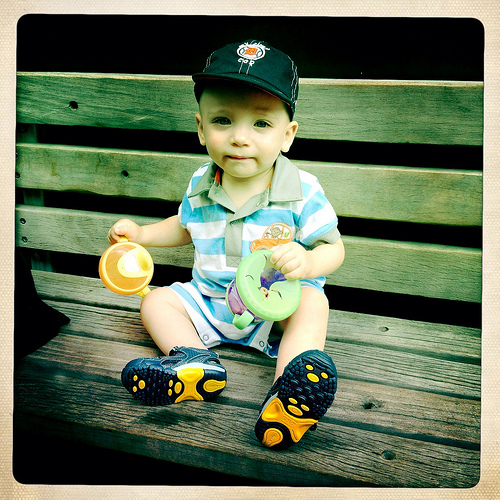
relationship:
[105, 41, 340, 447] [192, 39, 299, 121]
boy wearing baseball cap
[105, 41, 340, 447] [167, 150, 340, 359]
boy wearing onesie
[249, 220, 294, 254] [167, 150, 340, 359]
design sewed onto onesie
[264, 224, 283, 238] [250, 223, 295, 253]
monkey driving design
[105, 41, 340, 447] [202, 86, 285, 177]
boy has face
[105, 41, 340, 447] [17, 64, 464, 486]
boy sitting on bench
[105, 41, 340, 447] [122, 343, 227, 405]
boy has shoe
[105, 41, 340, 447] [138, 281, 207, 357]
boy has leg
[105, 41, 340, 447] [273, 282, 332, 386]
boy has leg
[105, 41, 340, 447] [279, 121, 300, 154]
boy has ear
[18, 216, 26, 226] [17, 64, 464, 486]
screws screwed in bench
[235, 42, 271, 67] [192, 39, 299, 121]
logo on front of baseball cap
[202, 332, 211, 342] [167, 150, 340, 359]
snap on front of onesie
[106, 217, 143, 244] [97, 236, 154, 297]
hand holding sippy cup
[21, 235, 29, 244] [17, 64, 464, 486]
screws screwed in bench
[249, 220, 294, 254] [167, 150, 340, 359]
design on front of onesie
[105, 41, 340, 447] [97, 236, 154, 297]
boy holding sippy cup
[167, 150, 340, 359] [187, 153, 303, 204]
onesie has collar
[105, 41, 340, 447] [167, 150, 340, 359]
boy has onesie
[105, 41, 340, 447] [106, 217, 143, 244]
boy using hand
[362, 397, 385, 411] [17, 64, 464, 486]
knot in middle of bench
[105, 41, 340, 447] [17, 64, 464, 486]
boy on bench